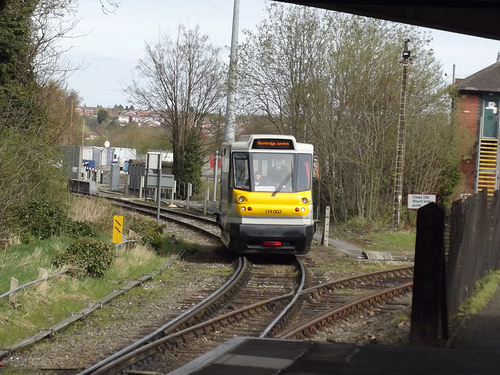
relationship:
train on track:
[199, 141, 324, 260] [201, 171, 291, 372]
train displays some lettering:
[199, 141, 324, 260] [252, 135, 291, 153]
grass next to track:
[315, 251, 351, 275] [201, 171, 291, 372]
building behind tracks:
[80, 138, 256, 200] [115, 188, 223, 247]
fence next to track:
[386, 196, 498, 355] [201, 171, 291, 372]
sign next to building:
[402, 191, 444, 213] [442, 64, 500, 179]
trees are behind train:
[254, 55, 396, 209] [199, 141, 324, 260]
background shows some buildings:
[72, 52, 336, 190] [80, 138, 256, 200]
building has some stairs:
[442, 64, 500, 179] [473, 135, 497, 207]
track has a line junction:
[201, 171, 291, 372] [217, 282, 332, 341]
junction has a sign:
[162, 256, 295, 360] [112, 215, 123, 244]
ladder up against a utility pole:
[387, 74, 404, 228] [387, 38, 413, 222]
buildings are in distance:
[80, 138, 256, 200] [72, 52, 336, 190]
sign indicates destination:
[243, 132, 306, 160] [257, 139, 287, 149]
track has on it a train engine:
[201, 171, 291, 372] [199, 141, 324, 260]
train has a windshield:
[199, 141, 324, 260] [234, 154, 310, 198]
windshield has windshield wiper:
[234, 154, 310, 198] [271, 173, 292, 197]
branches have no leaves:
[246, 25, 381, 123] [257, 26, 297, 56]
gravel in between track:
[307, 259, 347, 279] [201, 171, 291, 372]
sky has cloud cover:
[78, 27, 149, 69] [73, 14, 191, 35]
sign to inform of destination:
[243, 132, 306, 160] [257, 139, 287, 149]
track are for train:
[201, 171, 291, 372] [199, 141, 324, 260]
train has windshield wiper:
[199, 141, 324, 260] [265, 171, 297, 201]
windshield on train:
[234, 154, 310, 198] [199, 141, 324, 260]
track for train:
[201, 171, 291, 372] [199, 141, 324, 260]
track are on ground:
[201, 171, 291, 372] [147, 257, 369, 344]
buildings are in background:
[83, 118, 186, 196] [72, 52, 336, 190]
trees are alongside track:
[254, 55, 396, 209] [201, 171, 291, 372]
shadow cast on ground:
[165, 215, 236, 274] [147, 257, 369, 344]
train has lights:
[199, 141, 324, 260] [237, 185, 313, 217]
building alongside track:
[442, 64, 500, 179] [201, 171, 291, 372]